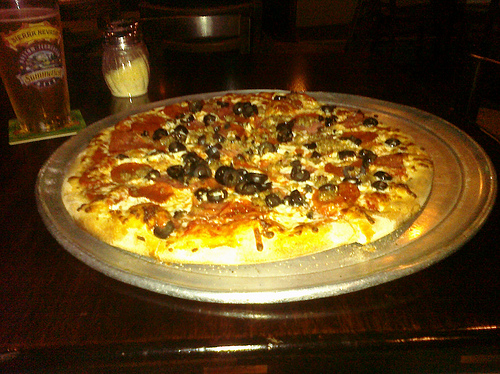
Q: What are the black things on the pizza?
A: Olives.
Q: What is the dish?
A: Pizza.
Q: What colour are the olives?
A: Black.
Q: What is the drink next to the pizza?
A: Beer.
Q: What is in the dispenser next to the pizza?
A: Cheese.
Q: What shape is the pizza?
A: Circle.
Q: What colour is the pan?
A: Silver.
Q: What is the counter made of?
A: Wood.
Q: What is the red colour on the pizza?
A: Tomatoes.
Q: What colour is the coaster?
A: Green.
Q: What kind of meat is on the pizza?
A: Pepperoni.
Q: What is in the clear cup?
A: Light brown beer.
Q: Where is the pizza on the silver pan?
A: Left side.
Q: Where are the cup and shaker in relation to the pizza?
A: Left.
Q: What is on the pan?
A: Pizza.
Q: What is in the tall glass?
A: Beer.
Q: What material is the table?
A: Wood.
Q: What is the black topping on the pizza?
A: Olives.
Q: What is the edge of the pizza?
A: Golden brown crust.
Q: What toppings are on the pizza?
A: Pepperoni, cheese, and black olives.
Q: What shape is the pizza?
A: Circle.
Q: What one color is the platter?
A: Silver.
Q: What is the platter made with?
A: Metal.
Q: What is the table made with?
A: Wood.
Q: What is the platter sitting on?
A: A table.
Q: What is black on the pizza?
A: Olives.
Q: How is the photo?
A: Clear.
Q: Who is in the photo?
A: Nobody.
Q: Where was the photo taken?
A: At a restaurant.